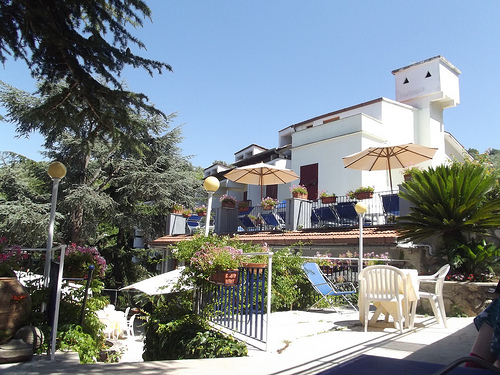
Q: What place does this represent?
A: It represents the garden.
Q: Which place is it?
A: It is a garden.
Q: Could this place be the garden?
A: Yes, it is the garden.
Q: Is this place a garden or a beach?
A: It is a garden.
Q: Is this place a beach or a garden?
A: It is a garden.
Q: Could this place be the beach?
A: No, it is the garden.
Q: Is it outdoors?
A: Yes, it is outdoors.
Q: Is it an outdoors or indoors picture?
A: It is outdoors.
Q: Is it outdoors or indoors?
A: It is outdoors.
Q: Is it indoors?
A: No, it is outdoors.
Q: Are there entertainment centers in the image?
A: No, there are no entertainment centers.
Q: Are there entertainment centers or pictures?
A: No, there are no entertainment centers or pictures.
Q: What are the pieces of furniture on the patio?
A: The pieces of furniture are chairs.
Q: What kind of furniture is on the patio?
A: The pieces of furniture are chairs.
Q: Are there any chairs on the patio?
A: Yes, there are chairs on the patio.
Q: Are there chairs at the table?
A: Yes, there are chairs at the table.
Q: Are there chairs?
A: Yes, there is a chair.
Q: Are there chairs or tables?
A: Yes, there is a chair.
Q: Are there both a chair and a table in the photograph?
A: Yes, there are both a chair and a table.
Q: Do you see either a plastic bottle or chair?
A: Yes, there is a plastic chair.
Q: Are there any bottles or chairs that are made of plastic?
A: Yes, the chair is made of plastic.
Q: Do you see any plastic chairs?
A: Yes, there is a chair that is made of plastic.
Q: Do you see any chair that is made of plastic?
A: Yes, there is a chair that is made of plastic.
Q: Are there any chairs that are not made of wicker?
A: Yes, there is a chair that is made of plastic.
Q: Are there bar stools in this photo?
A: No, there are no bar stools.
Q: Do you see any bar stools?
A: No, there are no bar stools.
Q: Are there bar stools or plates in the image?
A: No, there are no bar stools or plates.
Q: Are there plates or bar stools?
A: No, there are no bar stools or plates.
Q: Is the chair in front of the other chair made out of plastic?
A: Yes, the chair is made of plastic.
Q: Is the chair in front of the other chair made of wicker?
A: No, the chair is made of plastic.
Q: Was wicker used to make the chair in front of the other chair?
A: No, the chair is made of plastic.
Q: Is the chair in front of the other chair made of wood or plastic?
A: The chair is made of plastic.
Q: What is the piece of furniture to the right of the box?
A: The piece of furniture is a chair.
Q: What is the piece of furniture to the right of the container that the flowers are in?
A: The piece of furniture is a chair.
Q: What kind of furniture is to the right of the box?
A: The piece of furniture is a chair.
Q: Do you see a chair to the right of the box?
A: Yes, there is a chair to the right of the box.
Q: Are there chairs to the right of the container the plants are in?
A: Yes, there is a chair to the right of the box.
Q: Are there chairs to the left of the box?
A: No, the chair is to the right of the box.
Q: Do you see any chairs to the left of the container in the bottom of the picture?
A: No, the chair is to the right of the box.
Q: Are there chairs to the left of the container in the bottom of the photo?
A: No, the chair is to the right of the box.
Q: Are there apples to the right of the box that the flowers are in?
A: No, there is a chair to the right of the box.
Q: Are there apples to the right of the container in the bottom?
A: No, there is a chair to the right of the box.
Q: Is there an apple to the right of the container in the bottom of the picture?
A: No, there is a chair to the right of the box.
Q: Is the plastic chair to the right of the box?
A: Yes, the chair is to the right of the box.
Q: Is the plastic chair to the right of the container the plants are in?
A: Yes, the chair is to the right of the box.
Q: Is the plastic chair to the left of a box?
A: No, the chair is to the right of a box.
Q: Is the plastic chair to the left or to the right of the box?
A: The chair is to the right of the box.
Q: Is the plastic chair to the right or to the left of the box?
A: The chair is to the right of the box.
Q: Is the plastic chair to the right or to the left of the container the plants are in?
A: The chair is to the right of the box.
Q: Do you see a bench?
A: No, there are no benches.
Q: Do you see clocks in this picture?
A: No, there are no clocks.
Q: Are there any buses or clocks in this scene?
A: No, there are no clocks or buses.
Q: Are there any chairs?
A: Yes, there is a chair.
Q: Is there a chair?
A: Yes, there is a chair.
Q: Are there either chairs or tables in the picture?
A: Yes, there is a chair.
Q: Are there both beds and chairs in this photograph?
A: No, there is a chair but no beds.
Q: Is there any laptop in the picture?
A: No, there are no laptops.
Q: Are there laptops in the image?
A: No, there are no laptops.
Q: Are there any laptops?
A: No, there are no laptops.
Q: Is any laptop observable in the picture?
A: No, there are no laptops.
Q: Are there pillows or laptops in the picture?
A: No, there are no laptops or pillows.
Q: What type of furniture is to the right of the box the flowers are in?
A: The piece of furniture is a chair.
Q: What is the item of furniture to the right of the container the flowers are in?
A: The piece of furniture is a chair.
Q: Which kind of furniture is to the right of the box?
A: The piece of furniture is a chair.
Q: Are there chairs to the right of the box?
A: Yes, there is a chair to the right of the box.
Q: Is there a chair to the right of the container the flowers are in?
A: Yes, there is a chair to the right of the box.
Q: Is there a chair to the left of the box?
A: No, the chair is to the right of the box.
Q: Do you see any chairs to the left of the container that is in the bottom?
A: No, the chair is to the right of the box.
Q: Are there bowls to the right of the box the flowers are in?
A: No, there is a chair to the right of the box.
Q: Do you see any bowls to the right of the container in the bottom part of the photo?
A: No, there is a chair to the right of the box.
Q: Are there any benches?
A: No, there are no benches.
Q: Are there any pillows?
A: No, there are no pillows.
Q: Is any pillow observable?
A: No, there are no pillows.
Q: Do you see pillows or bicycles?
A: No, there are no pillows or bicycles.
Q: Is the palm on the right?
A: Yes, the palm is on the right of the image.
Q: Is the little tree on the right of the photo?
A: Yes, the palm is on the right of the image.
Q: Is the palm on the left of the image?
A: No, the palm is on the right of the image.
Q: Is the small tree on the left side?
A: No, the palm is on the right of the image.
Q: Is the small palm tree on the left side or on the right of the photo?
A: The palm is on the right of the image.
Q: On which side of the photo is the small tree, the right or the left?
A: The palm is on the right of the image.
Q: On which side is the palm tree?
A: The palm tree is on the right of the image.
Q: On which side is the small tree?
A: The palm tree is on the right of the image.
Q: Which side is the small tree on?
A: The palm tree is on the right of the image.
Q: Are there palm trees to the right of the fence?
A: Yes, there is a palm tree to the right of the fence.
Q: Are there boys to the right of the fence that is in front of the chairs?
A: No, there is a palm tree to the right of the fence.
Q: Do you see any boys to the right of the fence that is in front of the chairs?
A: No, there is a palm tree to the right of the fence.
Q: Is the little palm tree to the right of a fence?
A: Yes, the palm tree is to the right of a fence.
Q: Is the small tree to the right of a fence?
A: Yes, the palm tree is to the right of a fence.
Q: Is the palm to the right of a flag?
A: No, the palm is to the right of a fence.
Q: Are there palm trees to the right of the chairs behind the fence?
A: Yes, there is a palm tree to the right of the chairs.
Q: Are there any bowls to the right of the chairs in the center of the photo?
A: No, there is a palm tree to the right of the chairs.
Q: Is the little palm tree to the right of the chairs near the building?
A: Yes, the palm is to the right of the chairs.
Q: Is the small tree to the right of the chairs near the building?
A: Yes, the palm is to the right of the chairs.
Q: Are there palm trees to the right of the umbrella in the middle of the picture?
A: Yes, there is a palm tree to the right of the umbrella.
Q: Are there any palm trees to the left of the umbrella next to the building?
A: No, the palm tree is to the right of the umbrella.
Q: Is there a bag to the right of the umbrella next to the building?
A: No, there is a palm tree to the right of the umbrella.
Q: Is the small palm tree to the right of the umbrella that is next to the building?
A: Yes, the palm tree is to the right of the umbrella.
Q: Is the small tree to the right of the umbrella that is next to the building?
A: Yes, the palm tree is to the right of the umbrella.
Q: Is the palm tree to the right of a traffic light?
A: No, the palm tree is to the right of the umbrella.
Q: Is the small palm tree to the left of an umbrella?
A: No, the palm is to the right of an umbrella.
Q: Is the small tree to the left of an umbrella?
A: No, the palm is to the right of an umbrella.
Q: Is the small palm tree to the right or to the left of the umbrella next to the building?
A: The palm is to the right of the umbrella.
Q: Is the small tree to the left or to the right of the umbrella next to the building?
A: The palm is to the right of the umbrella.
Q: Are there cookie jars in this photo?
A: No, there are no cookie jars.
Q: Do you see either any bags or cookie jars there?
A: No, there are no cookie jars or bags.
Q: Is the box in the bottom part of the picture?
A: Yes, the box is in the bottom of the image.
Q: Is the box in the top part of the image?
A: No, the box is in the bottom of the image.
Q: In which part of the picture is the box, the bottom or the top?
A: The box is in the bottom of the image.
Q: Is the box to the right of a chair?
A: No, the box is to the left of a chair.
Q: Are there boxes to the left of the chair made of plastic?
A: Yes, there is a box to the left of the chair.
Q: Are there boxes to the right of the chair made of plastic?
A: No, the box is to the left of the chair.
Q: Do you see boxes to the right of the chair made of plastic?
A: No, the box is to the left of the chair.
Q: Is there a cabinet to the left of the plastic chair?
A: No, there is a box to the left of the chair.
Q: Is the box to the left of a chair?
A: Yes, the box is to the left of a chair.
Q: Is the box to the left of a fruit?
A: No, the box is to the left of a chair.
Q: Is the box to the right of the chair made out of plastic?
A: No, the box is to the left of the chair.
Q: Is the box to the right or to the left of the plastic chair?
A: The box is to the left of the chair.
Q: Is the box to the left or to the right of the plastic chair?
A: The box is to the left of the chair.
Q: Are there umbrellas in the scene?
A: Yes, there is an umbrella.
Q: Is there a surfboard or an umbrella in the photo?
A: Yes, there is an umbrella.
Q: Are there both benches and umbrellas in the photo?
A: No, there is an umbrella but no benches.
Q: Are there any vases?
A: No, there are no vases.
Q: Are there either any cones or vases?
A: No, there are no vases or cones.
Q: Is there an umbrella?
A: Yes, there is an umbrella.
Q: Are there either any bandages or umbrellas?
A: Yes, there is an umbrella.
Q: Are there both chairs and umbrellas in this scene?
A: Yes, there are both an umbrella and a chair.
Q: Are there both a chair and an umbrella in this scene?
A: Yes, there are both an umbrella and a chair.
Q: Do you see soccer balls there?
A: No, there are no soccer balls.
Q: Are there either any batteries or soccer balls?
A: No, there are no soccer balls or batteries.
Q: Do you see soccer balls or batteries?
A: No, there are no soccer balls or batteries.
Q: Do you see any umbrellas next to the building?
A: Yes, there is an umbrella next to the building.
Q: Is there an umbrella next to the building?
A: Yes, there is an umbrella next to the building.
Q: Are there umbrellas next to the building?
A: Yes, there is an umbrella next to the building.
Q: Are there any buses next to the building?
A: No, there is an umbrella next to the building.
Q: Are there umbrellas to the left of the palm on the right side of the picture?
A: Yes, there is an umbrella to the left of the palm.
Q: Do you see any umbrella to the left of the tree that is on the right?
A: Yes, there is an umbrella to the left of the palm.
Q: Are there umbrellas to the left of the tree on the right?
A: Yes, there is an umbrella to the left of the palm.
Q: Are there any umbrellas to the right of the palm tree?
A: No, the umbrella is to the left of the palm tree.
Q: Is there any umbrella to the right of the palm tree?
A: No, the umbrella is to the left of the palm tree.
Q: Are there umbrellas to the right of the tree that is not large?
A: No, the umbrella is to the left of the palm tree.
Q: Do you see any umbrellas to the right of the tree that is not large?
A: No, the umbrella is to the left of the palm tree.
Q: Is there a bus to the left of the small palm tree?
A: No, there is an umbrella to the left of the palm tree.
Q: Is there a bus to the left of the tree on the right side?
A: No, there is an umbrella to the left of the palm tree.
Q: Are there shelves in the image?
A: No, there are no shelves.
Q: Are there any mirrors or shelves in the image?
A: No, there are no shelves or mirrors.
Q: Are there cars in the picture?
A: No, there are no cars.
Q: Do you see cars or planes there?
A: No, there are no cars or planes.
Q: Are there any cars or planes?
A: No, there are no cars or planes.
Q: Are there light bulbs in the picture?
A: No, there are no light bulbs.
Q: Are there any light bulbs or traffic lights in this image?
A: No, there are no light bulbs or traffic lights.